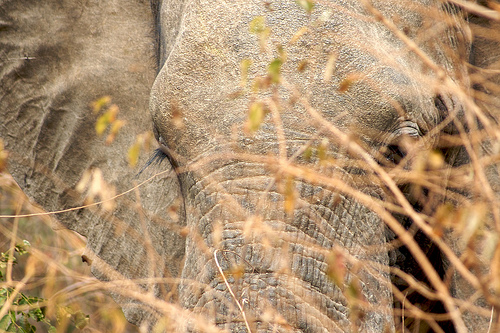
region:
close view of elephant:
[0, 3, 498, 332]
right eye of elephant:
[149, 139, 181, 184]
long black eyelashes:
[150, 143, 168, 168]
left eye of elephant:
[377, 122, 427, 166]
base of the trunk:
[177, 137, 391, 330]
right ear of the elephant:
[0, 2, 185, 329]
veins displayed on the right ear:
[2, 68, 90, 184]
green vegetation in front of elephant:
[2, 238, 87, 331]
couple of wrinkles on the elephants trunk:
[265, 219, 327, 246]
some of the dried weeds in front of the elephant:
[412, 13, 498, 331]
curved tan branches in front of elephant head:
[12, 15, 485, 320]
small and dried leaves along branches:
[85, 36, 310, 196]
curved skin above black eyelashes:
[130, 40, 175, 185]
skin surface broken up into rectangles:
[196, 167, 357, 313]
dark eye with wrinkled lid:
[380, 120, 420, 165]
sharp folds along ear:
[2, 1, 89, 213]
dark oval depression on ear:
[10, 36, 70, 91]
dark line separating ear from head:
[145, 0, 165, 70]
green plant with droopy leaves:
[0, 231, 95, 326]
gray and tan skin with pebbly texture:
[191, 18, 376, 111]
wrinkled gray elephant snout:
[181, 3, 390, 332]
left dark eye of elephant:
[376, 118, 426, 180]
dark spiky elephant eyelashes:
[137, 133, 179, 185]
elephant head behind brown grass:
[133, 3, 467, 329]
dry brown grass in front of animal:
[140, 83, 481, 331]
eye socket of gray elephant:
[146, 50, 190, 212]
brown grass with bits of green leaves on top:
[228, 8, 351, 160]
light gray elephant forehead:
[181, 9, 398, 103]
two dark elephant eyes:
[151, 116, 422, 177]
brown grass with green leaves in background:
[3, 282, 55, 329]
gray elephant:
[8, 12, 488, 309]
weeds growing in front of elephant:
[15, 29, 499, 321]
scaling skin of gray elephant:
[14, 14, 476, 328]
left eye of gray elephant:
[379, 119, 427, 173]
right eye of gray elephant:
[145, 130, 171, 154]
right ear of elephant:
[2, 5, 178, 300]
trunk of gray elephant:
[175, 154, 375, 331]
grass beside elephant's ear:
[1, 237, 92, 330]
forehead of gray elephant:
[173, 4, 380, 99]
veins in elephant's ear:
[0, 23, 92, 260]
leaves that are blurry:
[92, 93, 127, 146]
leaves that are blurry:
[232, 83, 266, 140]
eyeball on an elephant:
[149, 67, 190, 158]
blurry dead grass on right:
[428, 14, 475, 90]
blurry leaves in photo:
[330, 250, 378, 327]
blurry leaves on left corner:
[30, 241, 114, 315]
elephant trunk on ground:
[191, 146, 378, 326]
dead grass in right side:
[433, 7, 474, 70]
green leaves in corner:
[6, 316, 34, 331]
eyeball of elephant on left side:
[391, 106, 426, 183]